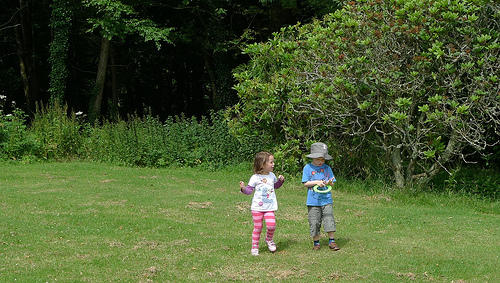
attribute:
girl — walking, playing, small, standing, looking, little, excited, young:
[238, 150, 285, 256]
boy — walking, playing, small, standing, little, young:
[302, 142, 342, 250]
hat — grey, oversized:
[304, 142, 333, 160]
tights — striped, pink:
[251, 209, 277, 249]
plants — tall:
[126, 106, 163, 168]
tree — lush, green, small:
[228, 0, 500, 193]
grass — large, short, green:
[2, 164, 500, 276]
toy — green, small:
[313, 183, 333, 194]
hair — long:
[252, 150, 274, 174]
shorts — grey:
[307, 205, 335, 237]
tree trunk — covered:
[49, 1, 69, 113]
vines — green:
[50, 8, 73, 18]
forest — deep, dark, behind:
[1, 1, 243, 128]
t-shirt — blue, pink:
[302, 163, 338, 207]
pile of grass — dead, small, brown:
[186, 199, 214, 211]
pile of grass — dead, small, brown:
[234, 199, 251, 214]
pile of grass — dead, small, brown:
[146, 265, 160, 277]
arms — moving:
[238, 175, 256, 195]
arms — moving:
[273, 173, 285, 190]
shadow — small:
[258, 238, 299, 253]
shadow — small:
[315, 237, 352, 251]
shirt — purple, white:
[240, 171, 284, 211]